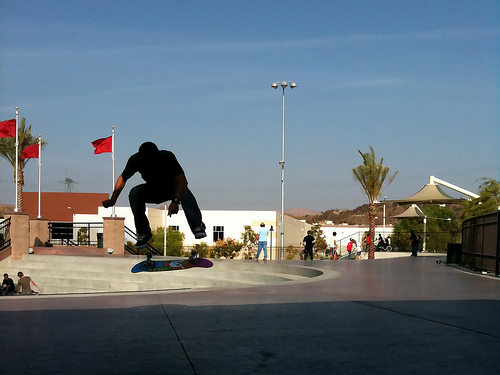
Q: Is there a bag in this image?
A: No, there are no bags.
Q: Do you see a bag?
A: No, there are no bags.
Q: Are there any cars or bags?
A: No, there are no bags or cars.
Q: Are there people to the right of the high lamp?
A: Yes, there are people to the right of the lamp.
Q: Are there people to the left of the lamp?
A: No, the people are to the right of the lamp.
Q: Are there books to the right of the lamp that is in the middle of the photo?
A: No, there are people to the right of the lamp.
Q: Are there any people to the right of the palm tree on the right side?
A: Yes, there are people to the right of the palm.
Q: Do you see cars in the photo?
A: No, there are no cars.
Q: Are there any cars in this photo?
A: No, there are no cars.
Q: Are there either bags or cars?
A: No, there are no cars or bags.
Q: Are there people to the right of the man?
A: Yes, there are people to the right of the man.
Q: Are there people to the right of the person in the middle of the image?
A: Yes, there are people to the right of the man.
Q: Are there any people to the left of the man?
A: No, the people are to the right of the man.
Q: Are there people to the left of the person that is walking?
A: No, the people are to the right of the man.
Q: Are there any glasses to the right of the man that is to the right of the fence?
A: No, there are people to the right of the man.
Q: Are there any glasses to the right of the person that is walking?
A: No, there are people to the right of the man.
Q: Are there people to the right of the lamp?
A: Yes, there are people to the right of the lamp.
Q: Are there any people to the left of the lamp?
A: No, the people are to the right of the lamp.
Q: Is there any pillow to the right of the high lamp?
A: No, there are people to the right of the lamp.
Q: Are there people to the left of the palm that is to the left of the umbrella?
A: Yes, there are people to the left of the palm.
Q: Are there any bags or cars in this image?
A: No, there are no cars or bags.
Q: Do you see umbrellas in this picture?
A: Yes, there is an umbrella.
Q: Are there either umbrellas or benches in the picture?
A: Yes, there is an umbrella.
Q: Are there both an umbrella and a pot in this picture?
A: No, there is an umbrella but no pots.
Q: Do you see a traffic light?
A: No, there are no traffic lights.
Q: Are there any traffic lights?
A: No, there are no traffic lights.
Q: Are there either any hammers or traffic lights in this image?
A: No, there are no traffic lights or hammers.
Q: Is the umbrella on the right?
A: Yes, the umbrella is on the right of the image.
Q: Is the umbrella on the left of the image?
A: No, the umbrella is on the right of the image.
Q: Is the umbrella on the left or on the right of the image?
A: The umbrella is on the right of the image.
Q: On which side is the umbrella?
A: The umbrella is on the right of the image.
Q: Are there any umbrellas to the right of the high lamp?
A: Yes, there is an umbrella to the right of the lamp.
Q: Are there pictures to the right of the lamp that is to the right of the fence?
A: No, there is an umbrella to the right of the lamp.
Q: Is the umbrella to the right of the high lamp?
A: Yes, the umbrella is to the right of the lamp.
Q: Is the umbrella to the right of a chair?
A: No, the umbrella is to the right of the lamp.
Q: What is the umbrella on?
A: The umbrella is on the pole.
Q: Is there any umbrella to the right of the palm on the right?
A: Yes, there is an umbrella to the right of the palm tree.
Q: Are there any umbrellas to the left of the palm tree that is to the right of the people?
A: No, the umbrella is to the right of the palm.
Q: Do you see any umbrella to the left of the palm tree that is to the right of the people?
A: No, the umbrella is to the right of the palm.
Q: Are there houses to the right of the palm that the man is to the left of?
A: No, there is an umbrella to the right of the palm tree.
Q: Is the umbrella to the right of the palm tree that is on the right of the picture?
A: Yes, the umbrella is to the right of the palm.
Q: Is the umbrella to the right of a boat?
A: No, the umbrella is to the right of the palm.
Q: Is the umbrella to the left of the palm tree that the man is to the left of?
A: No, the umbrella is to the right of the palm.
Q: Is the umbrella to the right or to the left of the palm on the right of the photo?
A: The umbrella is to the right of the palm.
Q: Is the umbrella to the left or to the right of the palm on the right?
A: The umbrella is to the right of the palm.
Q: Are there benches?
A: No, there are no benches.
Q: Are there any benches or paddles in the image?
A: No, there are no benches or paddles.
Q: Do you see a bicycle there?
A: No, there are no bicycles.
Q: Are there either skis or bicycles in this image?
A: No, there are no bicycles or skis.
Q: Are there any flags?
A: Yes, there is a flag.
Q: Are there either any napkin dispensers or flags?
A: Yes, there is a flag.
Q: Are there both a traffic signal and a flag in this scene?
A: No, there is a flag but no traffic lights.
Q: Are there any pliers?
A: No, there are no pliers.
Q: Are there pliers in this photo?
A: No, there are no pliers.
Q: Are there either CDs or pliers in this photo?
A: No, there are no pliers or cds.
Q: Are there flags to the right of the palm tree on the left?
A: Yes, there is a flag to the right of the palm tree.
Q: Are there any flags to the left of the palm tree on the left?
A: No, the flag is to the right of the palm tree.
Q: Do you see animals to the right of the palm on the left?
A: No, there is a flag to the right of the palm tree.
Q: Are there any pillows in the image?
A: No, there are no pillows.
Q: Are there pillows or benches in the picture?
A: No, there are no pillows or benches.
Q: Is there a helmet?
A: No, there are no helmets.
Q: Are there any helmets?
A: No, there are no helmets.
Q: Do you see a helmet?
A: No, there are no helmets.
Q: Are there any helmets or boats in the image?
A: No, there are no helmets or boats.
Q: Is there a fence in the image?
A: Yes, there is a fence.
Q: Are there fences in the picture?
A: Yes, there is a fence.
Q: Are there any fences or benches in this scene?
A: Yes, there is a fence.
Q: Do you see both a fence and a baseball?
A: No, there is a fence but no baseballs.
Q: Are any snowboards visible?
A: No, there are no snowboards.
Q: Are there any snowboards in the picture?
A: No, there are no snowboards.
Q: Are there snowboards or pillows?
A: No, there are no snowboards or pillows.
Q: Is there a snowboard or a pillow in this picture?
A: No, there are no snowboards or pillows.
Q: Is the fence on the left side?
A: Yes, the fence is on the left of the image.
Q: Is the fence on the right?
A: No, the fence is on the left of the image.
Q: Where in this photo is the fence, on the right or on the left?
A: The fence is on the left of the image.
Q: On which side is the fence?
A: The fence is on the left of the image.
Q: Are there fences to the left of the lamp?
A: Yes, there is a fence to the left of the lamp.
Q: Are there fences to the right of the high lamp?
A: No, the fence is to the left of the lamp.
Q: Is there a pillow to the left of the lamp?
A: No, there is a fence to the left of the lamp.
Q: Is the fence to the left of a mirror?
A: No, the fence is to the left of a lamp.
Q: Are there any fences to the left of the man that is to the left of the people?
A: Yes, there is a fence to the left of the man.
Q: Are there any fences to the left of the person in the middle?
A: Yes, there is a fence to the left of the man.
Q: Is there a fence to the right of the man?
A: No, the fence is to the left of the man.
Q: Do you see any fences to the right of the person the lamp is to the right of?
A: No, the fence is to the left of the man.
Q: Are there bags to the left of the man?
A: No, there is a fence to the left of the man.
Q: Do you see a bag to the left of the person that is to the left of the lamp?
A: No, there is a fence to the left of the man.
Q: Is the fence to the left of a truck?
A: No, the fence is to the left of a man.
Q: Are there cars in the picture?
A: No, there are no cars.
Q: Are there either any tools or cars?
A: No, there are no cars or tools.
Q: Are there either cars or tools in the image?
A: No, there are no cars or tools.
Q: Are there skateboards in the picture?
A: Yes, there is a skateboard.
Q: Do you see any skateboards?
A: Yes, there is a skateboard.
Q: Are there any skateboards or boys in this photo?
A: Yes, there is a skateboard.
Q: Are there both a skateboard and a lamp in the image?
A: Yes, there are both a skateboard and a lamp.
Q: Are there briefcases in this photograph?
A: No, there are no briefcases.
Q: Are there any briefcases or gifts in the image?
A: No, there are no briefcases or gifts.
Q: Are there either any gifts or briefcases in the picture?
A: No, there are no briefcases or gifts.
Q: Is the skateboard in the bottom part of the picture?
A: Yes, the skateboard is in the bottom of the image.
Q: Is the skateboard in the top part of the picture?
A: No, the skateboard is in the bottom of the image.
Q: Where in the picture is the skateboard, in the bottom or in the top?
A: The skateboard is in the bottom of the image.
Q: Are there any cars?
A: No, there are no cars.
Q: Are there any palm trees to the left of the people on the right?
A: Yes, there is a palm tree to the left of the people.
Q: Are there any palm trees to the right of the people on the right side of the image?
A: No, the palm tree is to the left of the people.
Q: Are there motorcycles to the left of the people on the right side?
A: No, there is a palm tree to the left of the people.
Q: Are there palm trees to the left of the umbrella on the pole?
A: Yes, there is a palm tree to the left of the umbrella.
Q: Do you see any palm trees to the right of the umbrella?
A: No, the palm tree is to the left of the umbrella.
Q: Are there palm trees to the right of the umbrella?
A: No, the palm tree is to the left of the umbrella.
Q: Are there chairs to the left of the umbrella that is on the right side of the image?
A: No, there is a palm tree to the left of the umbrella.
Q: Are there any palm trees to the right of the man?
A: Yes, there is a palm tree to the right of the man.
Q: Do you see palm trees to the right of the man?
A: Yes, there is a palm tree to the right of the man.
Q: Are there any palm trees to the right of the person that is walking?
A: Yes, there is a palm tree to the right of the man.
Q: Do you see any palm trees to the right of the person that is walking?
A: Yes, there is a palm tree to the right of the man.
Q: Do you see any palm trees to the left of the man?
A: No, the palm tree is to the right of the man.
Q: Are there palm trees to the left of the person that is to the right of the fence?
A: No, the palm tree is to the right of the man.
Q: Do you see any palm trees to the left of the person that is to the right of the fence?
A: No, the palm tree is to the right of the man.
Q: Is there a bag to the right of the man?
A: No, there is a palm tree to the right of the man.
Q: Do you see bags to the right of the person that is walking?
A: No, there is a palm tree to the right of the man.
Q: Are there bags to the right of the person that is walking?
A: No, there is a palm tree to the right of the man.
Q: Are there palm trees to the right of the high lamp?
A: Yes, there is a palm tree to the right of the lamp.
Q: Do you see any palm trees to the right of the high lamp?
A: Yes, there is a palm tree to the right of the lamp.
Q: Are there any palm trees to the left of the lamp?
A: No, the palm tree is to the right of the lamp.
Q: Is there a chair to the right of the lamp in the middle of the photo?
A: No, there is a palm tree to the right of the lamp.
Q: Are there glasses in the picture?
A: No, there are no glasses.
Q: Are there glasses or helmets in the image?
A: No, there are no glasses or helmets.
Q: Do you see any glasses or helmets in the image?
A: No, there are no glasses or helmets.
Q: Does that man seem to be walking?
A: Yes, the man is walking.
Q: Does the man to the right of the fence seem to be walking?
A: Yes, the man is walking.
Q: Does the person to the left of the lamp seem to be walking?
A: Yes, the man is walking.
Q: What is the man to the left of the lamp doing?
A: The man is walking.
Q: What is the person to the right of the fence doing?
A: The man is walking.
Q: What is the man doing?
A: The man is walking.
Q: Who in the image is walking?
A: The man is walking.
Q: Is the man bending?
A: No, the man is walking.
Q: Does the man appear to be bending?
A: No, the man is walking.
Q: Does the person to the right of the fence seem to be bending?
A: No, the man is walking.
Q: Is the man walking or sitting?
A: The man is walking.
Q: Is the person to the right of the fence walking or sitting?
A: The man is walking.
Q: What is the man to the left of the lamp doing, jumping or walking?
A: The man is walking.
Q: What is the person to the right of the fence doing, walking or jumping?
A: The man is walking.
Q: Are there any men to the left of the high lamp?
A: Yes, there is a man to the left of the lamp.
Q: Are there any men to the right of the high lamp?
A: No, the man is to the left of the lamp.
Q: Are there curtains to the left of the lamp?
A: No, there is a man to the left of the lamp.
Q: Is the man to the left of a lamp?
A: Yes, the man is to the left of a lamp.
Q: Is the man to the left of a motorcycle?
A: No, the man is to the left of a lamp.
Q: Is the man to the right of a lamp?
A: No, the man is to the left of a lamp.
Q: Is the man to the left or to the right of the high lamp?
A: The man is to the left of the lamp.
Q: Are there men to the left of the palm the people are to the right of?
A: Yes, there is a man to the left of the palm tree.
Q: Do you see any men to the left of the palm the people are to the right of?
A: Yes, there is a man to the left of the palm tree.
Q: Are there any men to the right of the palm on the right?
A: No, the man is to the left of the palm tree.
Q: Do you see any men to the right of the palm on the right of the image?
A: No, the man is to the left of the palm tree.